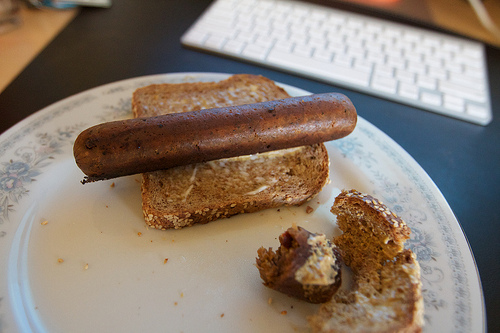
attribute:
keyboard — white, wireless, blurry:
[178, 0, 492, 127]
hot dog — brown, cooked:
[73, 91, 358, 181]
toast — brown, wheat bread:
[131, 72, 330, 230]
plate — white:
[0, 71, 489, 332]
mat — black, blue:
[0, 0, 499, 331]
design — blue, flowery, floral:
[329, 134, 447, 326]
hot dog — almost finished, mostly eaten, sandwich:
[255, 225, 342, 305]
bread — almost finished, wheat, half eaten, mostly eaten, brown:
[306, 187, 425, 332]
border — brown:
[0, 5, 83, 94]